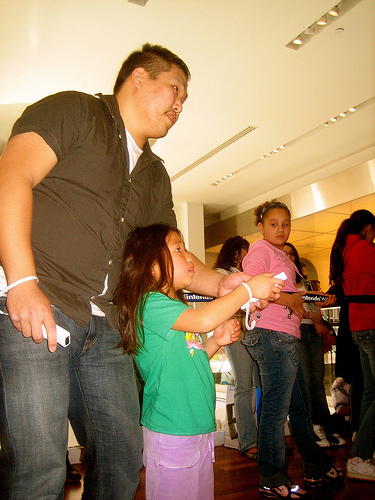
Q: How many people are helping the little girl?
A: One.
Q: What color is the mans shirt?
A: Green.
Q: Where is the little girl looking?
A: Up.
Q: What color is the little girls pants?
A: Pink.